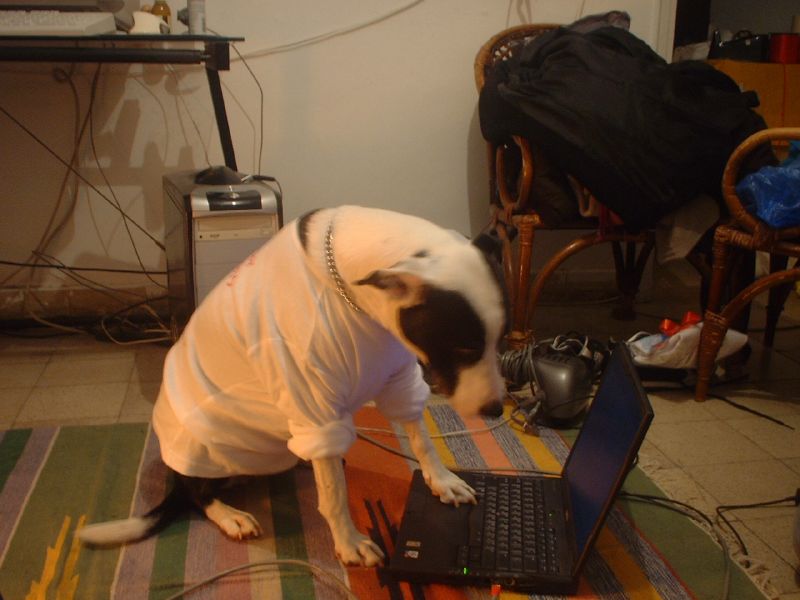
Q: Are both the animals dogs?
A: Yes, all the animals are dogs.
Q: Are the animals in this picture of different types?
A: No, all the animals are dogs.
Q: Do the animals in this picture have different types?
A: No, all the animals are dogs.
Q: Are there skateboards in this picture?
A: No, there are no skateboards.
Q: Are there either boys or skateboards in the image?
A: No, there are no skateboards or boys.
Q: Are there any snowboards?
A: No, there are no snowboards.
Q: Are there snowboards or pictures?
A: No, there are no snowboards or pictures.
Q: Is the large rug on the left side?
A: Yes, the rug is on the left of the image.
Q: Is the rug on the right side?
A: No, the rug is on the left of the image.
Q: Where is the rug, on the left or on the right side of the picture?
A: The rug is on the left of the image.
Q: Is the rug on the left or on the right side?
A: The rug is on the left of the image.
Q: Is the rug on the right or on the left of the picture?
A: The rug is on the left of the image.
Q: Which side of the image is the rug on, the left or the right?
A: The rug is on the left of the image.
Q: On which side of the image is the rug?
A: The rug is on the left of the image.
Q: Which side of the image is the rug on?
A: The rug is on the left of the image.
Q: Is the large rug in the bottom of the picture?
A: Yes, the rug is in the bottom of the image.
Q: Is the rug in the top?
A: No, the rug is in the bottom of the image.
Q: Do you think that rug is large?
A: Yes, the rug is large.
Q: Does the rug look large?
A: Yes, the rug is large.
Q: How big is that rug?
A: The rug is large.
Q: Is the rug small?
A: No, the rug is large.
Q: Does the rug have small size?
A: No, the rug is large.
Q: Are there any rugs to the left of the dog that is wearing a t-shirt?
A: Yes, there is a rug to the left of the dog.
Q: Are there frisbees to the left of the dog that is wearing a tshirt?
A: No, there is a rug to the left of the dog.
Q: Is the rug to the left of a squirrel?
A: No, the rug is to the left of a dog.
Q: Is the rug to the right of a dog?
A: No, the rug is to the left of a dog.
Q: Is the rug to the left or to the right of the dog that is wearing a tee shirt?
A: The rug is to the left of the dog.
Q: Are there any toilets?
A: No, there are no toilets.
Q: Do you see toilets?
A: No, there are no toilets.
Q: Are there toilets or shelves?
A: No, there are no toilets or shelves.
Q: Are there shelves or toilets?
A: No, there are no toilets or shelves.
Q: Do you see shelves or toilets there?
A: No, there are no toilets or shelves.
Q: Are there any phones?
A: No, there are no phones.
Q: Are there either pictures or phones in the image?
A: No, there are no phones or pictures.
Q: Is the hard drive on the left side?
A: Yes, the hard drive is on the left of the image.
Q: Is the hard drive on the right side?
A: No, the hard drive is on the left of the image.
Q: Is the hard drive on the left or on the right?
A: The hard drive is on the left of the image.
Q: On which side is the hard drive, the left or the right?
A: The hard drive is on the left of the image.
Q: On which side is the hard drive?
A: The hard drive is on the left of the image.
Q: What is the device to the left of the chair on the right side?
A: The device is a hard drive.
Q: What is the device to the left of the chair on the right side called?
A: The device is a hard drive.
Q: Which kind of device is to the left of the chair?
A: The device is a hard drive.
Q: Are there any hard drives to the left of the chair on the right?
A: Yes, there is a hard drive to the left of the chair.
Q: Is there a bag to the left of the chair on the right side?
A: No, there is a hard drive to the left of the chair.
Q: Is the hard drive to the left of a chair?
A: Yes, the hard drive is to the left of a chair.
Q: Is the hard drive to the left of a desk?
A: No, the hard drive is to the left of a chair.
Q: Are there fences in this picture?
A: No, there are no fences.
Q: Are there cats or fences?
A: No, there are no fences or cats.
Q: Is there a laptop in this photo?
A: Yes, there is a laptop.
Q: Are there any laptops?
A: Yes, there is a laptop.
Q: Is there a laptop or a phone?
A: Yes, there is a laptop.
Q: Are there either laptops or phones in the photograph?
A: Yes, there is a laptop.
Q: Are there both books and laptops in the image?
A: No, there is a laptop but no books.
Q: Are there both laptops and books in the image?
A: No, there is a laptop but no books.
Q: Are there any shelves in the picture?
A: No, there are no shelves.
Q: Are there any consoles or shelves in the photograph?
A: No, there are no shelves or consoles.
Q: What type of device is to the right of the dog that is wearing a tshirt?
A: The device is a laptop.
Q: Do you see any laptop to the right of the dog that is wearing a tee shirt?
A: Yes, there is a laptop to the right of the dog.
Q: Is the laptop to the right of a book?
A: No, the laptop is to the right of the dog.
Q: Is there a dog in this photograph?
A: Yes, there is a dog.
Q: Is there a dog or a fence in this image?
A: Yes, there is a dog.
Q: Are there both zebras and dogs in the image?
A: No, there is a dog but no zebras.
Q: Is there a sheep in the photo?
A: No, there is no sheep.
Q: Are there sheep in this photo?
A: No, there are no sheep.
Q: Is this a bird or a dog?
A: This is a dog.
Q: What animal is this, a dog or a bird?
A: This is a dog.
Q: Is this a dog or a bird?
A: This is a dog.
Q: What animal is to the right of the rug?
A: The animal is a dog.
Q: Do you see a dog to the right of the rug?
A: Yes, there is a dog to the right of the rug.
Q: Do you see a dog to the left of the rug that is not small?
A: No, the dog is to the right of the rug.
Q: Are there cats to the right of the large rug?
A: No, there is a dog to the right of the rug.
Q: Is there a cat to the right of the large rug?
A: No, there is a dog to the right of the rug.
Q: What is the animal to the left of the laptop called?
A: The animal is a dog.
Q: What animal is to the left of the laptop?
A: The animal is a dog.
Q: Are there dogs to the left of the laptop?
A: Yes, there is a dog to the left of the laptop.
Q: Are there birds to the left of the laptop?
A: No, there is a dog to the left of the laptop.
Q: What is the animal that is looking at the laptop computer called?
A: The animal is a dog.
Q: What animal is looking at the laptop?
A: The animal is a dog.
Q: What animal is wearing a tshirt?
A: The dog is wearing a tshirt.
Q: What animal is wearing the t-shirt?
A: The dog is wearing a tshirt.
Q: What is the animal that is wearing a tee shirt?
A: The animal is a dog.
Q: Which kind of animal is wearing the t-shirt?
A: The animal is a dog.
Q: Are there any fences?
A: No, there are no fences.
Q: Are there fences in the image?
A: No, there are no fences.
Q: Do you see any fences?
A: No, there are no fences.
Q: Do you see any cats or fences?
A: No, there are no fences or cats.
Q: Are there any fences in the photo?
A: No, there are no fences.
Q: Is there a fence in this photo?
A: No, there are no fences.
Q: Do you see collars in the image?
A: Yes, there is a collar.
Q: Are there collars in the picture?
A: Yes, there is a collar.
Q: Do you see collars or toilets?
A: Yes, there is a collar.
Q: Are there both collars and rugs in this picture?
A: Yes, there are both a collar and a rug.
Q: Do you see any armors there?
A: No, there are no armors.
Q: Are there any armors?
A: No, there are no armors.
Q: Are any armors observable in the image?
A: No, there are no armors.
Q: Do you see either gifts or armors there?
A: No, there are no armors or gifts.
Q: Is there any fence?
A: No, there are no fences.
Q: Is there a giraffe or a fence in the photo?
A: No, there are no fences or giraffes.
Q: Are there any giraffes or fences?
A: No, there are no fences or giraffes.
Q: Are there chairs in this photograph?
A: Yes, there is a chair.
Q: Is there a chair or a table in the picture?
A: Yes, there is a chair.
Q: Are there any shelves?
A: No, there are no shelves.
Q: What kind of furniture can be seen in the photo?
A: The furniture is a chair.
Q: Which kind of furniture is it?
A: The piece of furniture is a chair.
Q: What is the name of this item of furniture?
A: This is a chair.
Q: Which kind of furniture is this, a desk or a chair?
A: This is a chair.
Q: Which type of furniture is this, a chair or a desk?
A: This is a chair.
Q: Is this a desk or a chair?
A: This is a chair.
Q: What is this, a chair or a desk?
A: This is a chair.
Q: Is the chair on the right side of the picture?
A: Yes, the chair is on the right of the image.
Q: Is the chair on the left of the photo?
A: No, the chair is on the right of the image.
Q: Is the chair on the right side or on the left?
A: The chair is on the right of the image.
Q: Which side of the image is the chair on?
A: The chair is on the right of the image.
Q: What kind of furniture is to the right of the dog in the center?
A: The piece of furniture is a chair.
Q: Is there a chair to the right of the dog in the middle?
A: Yes, there is a chair to the right of the dog.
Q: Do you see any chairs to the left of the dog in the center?
A: No, the chair is to the right of the dog.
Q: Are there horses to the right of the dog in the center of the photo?
A: No, there is a chair to the right of the dog.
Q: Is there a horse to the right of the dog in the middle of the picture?
A: No, there is a chair to the right of the dog.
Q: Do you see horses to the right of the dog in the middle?
A: No, there is a chair to the right of the dog.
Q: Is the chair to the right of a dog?
A: Yes, the chair is to the right of a dog.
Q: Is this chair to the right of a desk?
A: No, the chair is to the right of a dog.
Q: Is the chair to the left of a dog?
A: No, the chair is to the right of a dog.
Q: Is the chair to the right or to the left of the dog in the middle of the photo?
A: The chair is to the right of the dog.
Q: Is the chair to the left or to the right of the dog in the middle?
A: The chair is to the right of the dog.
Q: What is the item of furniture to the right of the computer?
A: The piece of furniture is a chair.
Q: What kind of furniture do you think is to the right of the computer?
A: The piece of furniture is a chair.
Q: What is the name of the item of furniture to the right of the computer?
A: The piece of furniture is a chair.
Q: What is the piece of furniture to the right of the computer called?
A: The piece of furniture is a chair.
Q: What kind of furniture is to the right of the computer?
A: The piece of furniture is a chair.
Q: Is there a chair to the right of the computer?
A: Yes, there is a chair to the right of the computer.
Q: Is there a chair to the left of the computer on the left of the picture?
A: No, the chair is to the right of the computer.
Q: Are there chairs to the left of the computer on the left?
A: No, the chair is to the right of the computer.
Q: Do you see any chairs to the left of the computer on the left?
A: No, the chair is to the right of the computer.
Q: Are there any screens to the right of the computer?
A: No, there is a chair to the right of the computer.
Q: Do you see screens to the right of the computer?
A: No, there is a chair to the right of the computer.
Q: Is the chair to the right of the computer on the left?
A: Yes, the chair is to the right of the computer.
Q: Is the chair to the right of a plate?
A: No, the chair is to the right of the computer.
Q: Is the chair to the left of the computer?
A: No, the chair is to the right of the computer.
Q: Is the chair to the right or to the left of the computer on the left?
A: The chair is to the right of the computer.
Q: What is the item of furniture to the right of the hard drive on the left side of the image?
A: The piece of furniture is a chair.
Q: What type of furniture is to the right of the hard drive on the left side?
A: The piece of furniture is a chair.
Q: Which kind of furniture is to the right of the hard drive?
A: The piece of furniture is a chair.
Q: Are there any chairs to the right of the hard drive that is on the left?
A: Yes, there is a chair to the right of the hard drive.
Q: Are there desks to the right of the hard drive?
A: No, there is a chair to the right of the hard drive.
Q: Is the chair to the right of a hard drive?
A: Yes, the chair is to the right of a hard drive.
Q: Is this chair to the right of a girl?
A: No, the chair is to the right of a hard drive.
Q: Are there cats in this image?
A: No, there are no cats.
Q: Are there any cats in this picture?
A: No, there are no cats.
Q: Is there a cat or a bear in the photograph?
A: No, there are no cats or bears.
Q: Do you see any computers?
A: Yes, there is a computer.